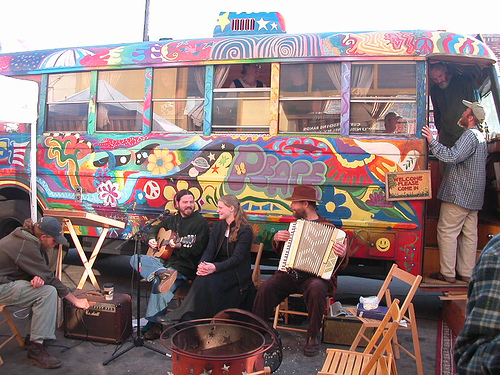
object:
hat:
[283, 185, 323, 203]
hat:
[462, 99, 486, 122]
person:
[144, 194, 255, 330]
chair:
[345, 264, 422, 375]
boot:
[428, 273, 447, 283]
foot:
[429, 273, 456, 283]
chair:
[248, 242, 265, 287]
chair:
[316, 298, 401, 375]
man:
[420, 100, 487, 284]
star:
[221, 364, 231, 374]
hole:
[222, 364, 229, 373]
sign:
[385, 170, 433, 202]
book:
[357, 303, 394, 322]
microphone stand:
[103, 233, 172, 366]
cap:
[39, 216, 68, 244]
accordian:
[277, 219, 347, 281]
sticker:
[375, 237, 391, 253]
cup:
[103, 283, 115, 300]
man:
[129, 189, 210, 340]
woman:
[222, 63, 268, 128]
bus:
[0, 11, 500, 293]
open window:
[213, 63, 272, 134]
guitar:
[146, 227, 198, 259]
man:
[0, 215, 90, 368]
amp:
[63, 289, 133, 345]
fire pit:
[160, 309, 284, 375]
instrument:
[278, 219, 347, 280]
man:
[248, 184, 348, 357]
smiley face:
[376, 238, 390, 252]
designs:
[22, 132, 420, 232]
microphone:
[114, 209, 170, 252]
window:
[278, 61, 341, 136]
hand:
[168, 239, 177, 249]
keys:
[278, 221, 298, 271]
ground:
[2, 251, 453, 373]